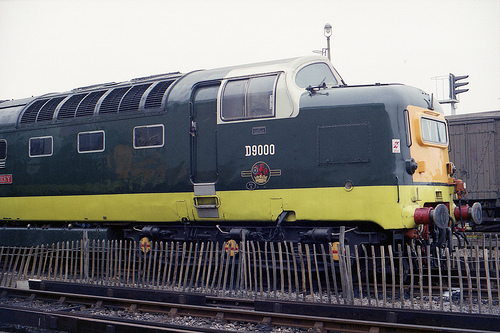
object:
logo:
[240, 160, 281, 190]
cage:
[430, 72, 470, 104]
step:
[188, 175, 221, 218]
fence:
[0, 226, 499, 328]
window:
[77, 130, 106, 154]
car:
[0, 54, 482, 262]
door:
[187, 79, 220, 183]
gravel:
[0, 294, 294, 333]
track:
[0, 272, 492, 332]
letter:
[244, 145, 251, 156]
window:
[132, 123, 165, 150]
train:
[1, 54, 483, 264]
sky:
[4, 1, 500, 115]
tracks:
[2, 236, 500, 301]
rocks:
[2, 298, 308, 333]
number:
[244, 144, 275, 157]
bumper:
[414, 203, 450, 229]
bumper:
[454, 202, 484, 225]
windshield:
[292, 60, 338, 89]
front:
[401, 104, 468, 185]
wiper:
[304, 76, 329, 95]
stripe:
[0, 184, 454, 231]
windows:
[28, 136, 52, 158]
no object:
[270, 175, 403, 310]